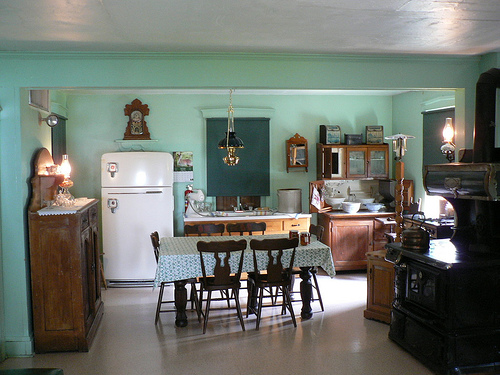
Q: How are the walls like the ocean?
A: Aqua.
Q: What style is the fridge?
A: Vintage.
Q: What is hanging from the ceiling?
A: Lamp.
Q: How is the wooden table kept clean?
A: Cloth surface.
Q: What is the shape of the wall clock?
A: Keyhole.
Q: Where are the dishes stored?
A: Buffet hutch.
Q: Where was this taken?
A: A kitchen.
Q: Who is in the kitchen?
A: No body.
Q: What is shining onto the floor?
A: Sunlight.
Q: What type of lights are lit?
A: Lanterns.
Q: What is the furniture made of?
A: Wood.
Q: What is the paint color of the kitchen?
A: Light green.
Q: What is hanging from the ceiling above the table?
A: A lamp.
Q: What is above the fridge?
A: A clock.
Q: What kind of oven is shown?
A: Wood burning.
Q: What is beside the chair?
A: Table.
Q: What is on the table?
A: Cloth.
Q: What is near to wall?
A: Fridge.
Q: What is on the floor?
A: Linoleum.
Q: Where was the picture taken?
A: In a kitchen.